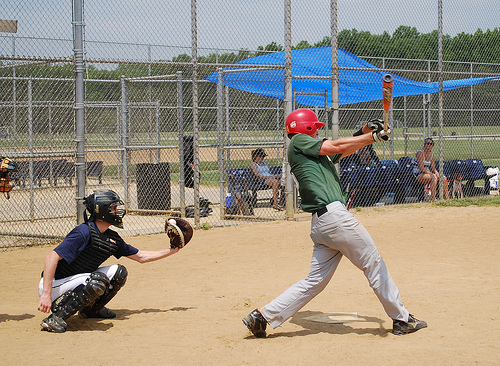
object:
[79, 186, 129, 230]
helmet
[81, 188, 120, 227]
head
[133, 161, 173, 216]
trash can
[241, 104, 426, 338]
player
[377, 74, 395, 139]
bat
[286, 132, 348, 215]
jersey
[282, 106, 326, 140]
helmet